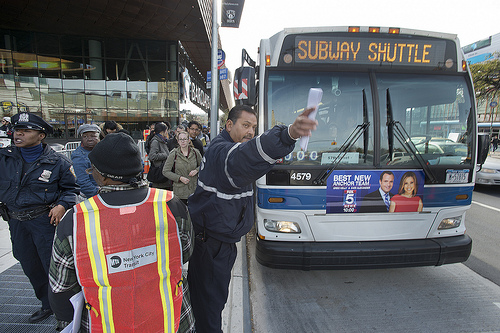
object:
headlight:
[437, 215, 460, 232]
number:
[289, 171, 311, 181]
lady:
[161, 132, 203, 206]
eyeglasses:
[177, 137, 187, 142]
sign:
[327, 164, 432, 213]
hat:
[92, 131, 143, 180]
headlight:
[262, 218, 301, 233]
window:
[152, 77, 165, 86]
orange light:
[346, 26, 364, 34]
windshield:
[263, 67, 476, 185]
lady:
[69, 121, 108, 202]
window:
[57, 34, 85, 58]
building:
[2, 1, 234, 142]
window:
[145, 59, 180, 83]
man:
[47, 132, 195, 332]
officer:
[0, 114, 77, 332]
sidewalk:
[0, 184, 232, 331]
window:
[3, 75, 177, 127]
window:
[104, 41, 131, 61]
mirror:
[473, 132, 490, 172]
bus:
[233, 25, 490, 270]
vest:
[71, 186, 182, 325]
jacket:
[162, 147, 200, 199]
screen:
[289, 35, 442, 70]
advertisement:
[314, 165, 421, 216]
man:
[184, 104, 317, 333]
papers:
[298, 88, 324, 151]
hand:
[287, 108, 318, 139]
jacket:
[187, 124, 295, 244]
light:
[264, 195, 284, 205]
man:
[356, 170, 396, 213]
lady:
[387, 172, 422, 213]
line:
[470, 199, 499, 218]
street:
[260, 186, 499, 331]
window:
[273, 73, 368, 162]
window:
[10, 56, 194, 134]